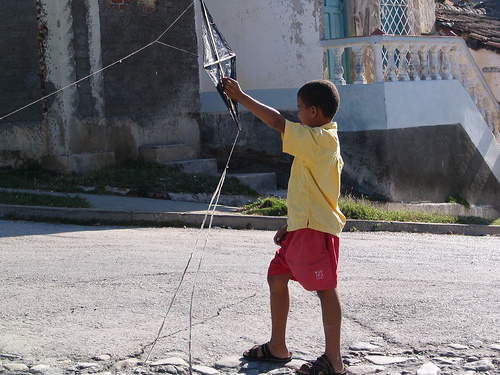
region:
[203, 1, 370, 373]
the little boy is flying a kite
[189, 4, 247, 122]
the little boy is holding a kite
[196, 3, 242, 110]
the kite is black in color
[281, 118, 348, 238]
the little boy is wearing a short sleeve shirt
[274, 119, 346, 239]
the shirt is yellow in color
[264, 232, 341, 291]
the little boy is wearing shorts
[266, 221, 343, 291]
the shorts are red in color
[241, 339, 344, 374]
the little boy is wearing sandals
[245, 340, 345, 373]
the sandals are brown in color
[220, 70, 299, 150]
the little boy has his arm raised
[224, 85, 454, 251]
a boy is in a yellow shirt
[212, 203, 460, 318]
the boy is in red shorts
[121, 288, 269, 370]
the ground is made of cement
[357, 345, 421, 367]
the ground is made of broken cement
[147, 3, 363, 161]
the boy is holding a kite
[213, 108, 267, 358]
the kite has a string attached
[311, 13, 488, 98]
a staircase is in the background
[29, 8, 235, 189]
a wall is faded black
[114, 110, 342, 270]
stairs lead to the wall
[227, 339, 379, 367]
the boy is wearing flip flops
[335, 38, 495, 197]
stairs in front of door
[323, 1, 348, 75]
green door on building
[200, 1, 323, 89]
worn white paint on wall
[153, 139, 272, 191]
three cement steps of building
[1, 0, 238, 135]
strings on front of kite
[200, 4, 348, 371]
boy with kite in hand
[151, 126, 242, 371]
tail on bottom of kite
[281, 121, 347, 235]
short sleeves on yellow shirt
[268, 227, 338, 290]
red shorts on body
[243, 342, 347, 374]
sandals on two feet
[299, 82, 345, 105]
Black hair in the photo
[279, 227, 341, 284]
Red shorts in the photo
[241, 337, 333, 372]
Shoes in the photo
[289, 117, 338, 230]
Cream shirt in the photo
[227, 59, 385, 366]
A child in the photo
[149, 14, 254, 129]
A kite in the photo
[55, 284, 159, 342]
Road with tarmac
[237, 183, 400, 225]
Grass in the photo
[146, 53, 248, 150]
Building in the photo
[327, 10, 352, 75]
A door in the photo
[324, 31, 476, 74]
white stair guardrails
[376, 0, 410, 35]
white metal grate over window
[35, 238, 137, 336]
grey concrete on ground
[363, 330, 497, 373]
grey rocks laying on concrete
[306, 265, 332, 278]
small white logo on leg of shorts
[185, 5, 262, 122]
black plastic kite being held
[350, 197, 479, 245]
grass growing on sidewalk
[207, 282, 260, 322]
large crack in concrete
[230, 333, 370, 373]
pair of brown sandals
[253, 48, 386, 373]
Child in yellow shirt